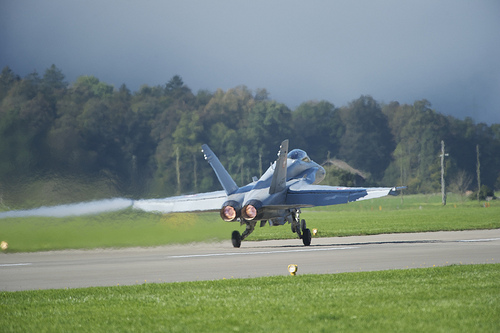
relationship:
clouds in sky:
[0, 0, 499, 126] [0, 2, 497, 139]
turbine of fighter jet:
[241, 202, 258, 223] [120, 116, 413, 246]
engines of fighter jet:
[221, 199, 243, 222] [120, 116, 413, 246]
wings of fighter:
[101, 182, 428, 211] [90, 128, 407, 258]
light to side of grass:
[287, 263, 297, 274] [6, 273, 498, 331]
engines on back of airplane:
[221, 194, 278, 239] [132, 138, 407, 247]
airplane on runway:
[132, 138, 407, 247] [1, 225, 498, 291]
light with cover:
[289, 263, 297, 274] [288, 264, 298, 274]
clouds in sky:
[191, 18, 360, 100] [0, 1, 498, 126]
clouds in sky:
[0, 0, 499, 126] [0, 1, 498, 126]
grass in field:
[0, 262, 498, 331] [0, 195, 497, 330]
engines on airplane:
[221, 199, 243, 222] [132, 138, 407, 247]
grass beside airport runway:
[0, 262, 498, 331] [0, 227, 498, 291]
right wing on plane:
[263, 177, 402, 210] [144, 137, 404, 247]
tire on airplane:
[231, 228, 243, 248] [141, 136, 408, 246]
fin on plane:
[199, 143, 238, 190] [128, 133, 398, 243]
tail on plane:
[197, 142, 304, 204] [128, 133, 398, 243]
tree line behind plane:
[1, 57, 499, 200] [119, 137, 407, 249]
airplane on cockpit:
[132, 138, 407, 247] [285, 145, 307, 161]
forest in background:
[6, 71, 497, 215] [3, 58, 497, 226]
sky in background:
[141, 16, 470, 111] [3, 22, 498, 122]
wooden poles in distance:
[438, 135, 454, 222] [4, 65, 494, 231]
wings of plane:
[288, 183, 410, 206] [156, 91, 426, 280]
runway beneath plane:
[3, 244, 435, 277] [134, 141, 408, 255]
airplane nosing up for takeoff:
[132, 138, 407, 247] [130, 122, 424, 245]